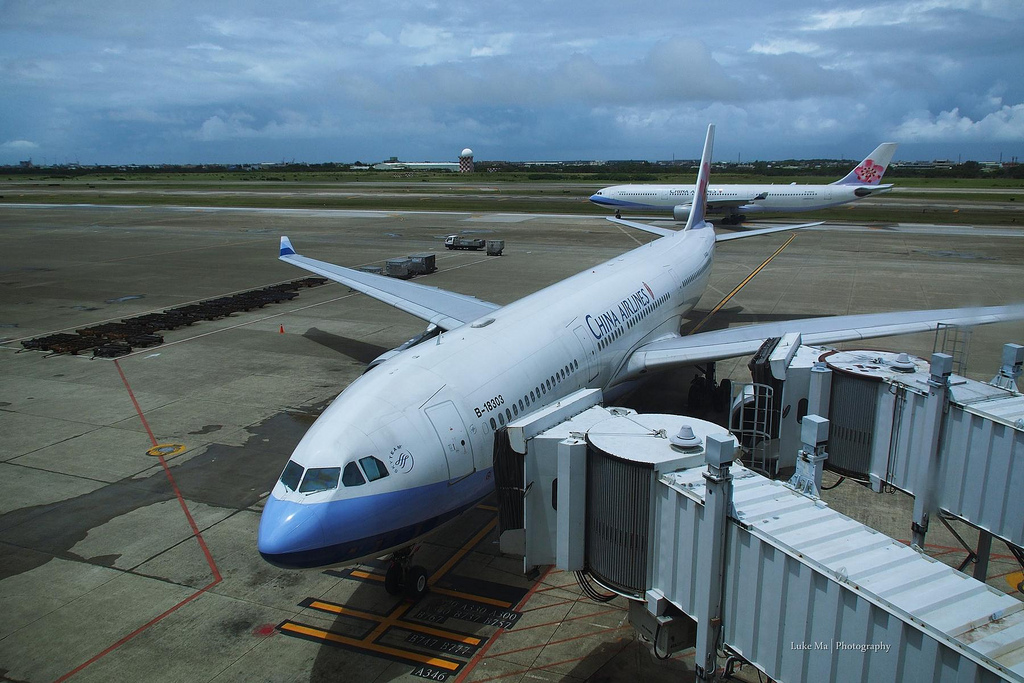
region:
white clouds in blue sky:
[40, 78, 107, 121]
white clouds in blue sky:
[292, 34, 359, 101]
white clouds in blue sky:
[122, 40, 186, 95]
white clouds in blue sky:
[245, 40, 323, 116]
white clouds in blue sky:
[672, 57, 800, 144]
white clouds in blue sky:
[599, 48, 666, 88]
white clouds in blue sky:
[418, 63, 496, 124]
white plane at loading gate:
[129, 153, 910, 628]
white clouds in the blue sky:
[59, 34, 151, 69]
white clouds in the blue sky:
[283, 43, 361, 86]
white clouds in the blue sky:
[256, 131, 339, 152]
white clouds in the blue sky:
[423, 17, 589, 122]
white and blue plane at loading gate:
[154, 124, 872, 586]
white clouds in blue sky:
[116, 28, 164, 66]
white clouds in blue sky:
[405, 78, 497, 113]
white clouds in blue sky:
[607, 48, 697, 105]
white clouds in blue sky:
[281, 28, 327, 71]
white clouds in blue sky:
[386, 53, 473, 117]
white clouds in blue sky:
[275, 72, 345, 127]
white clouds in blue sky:
[146, 40, 208, 105]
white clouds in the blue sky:
[286, 65, 367, 117]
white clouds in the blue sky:
[433, 30, 485, 78]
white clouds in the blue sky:
[596, 37, 648, 82]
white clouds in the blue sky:
[319, 42, 395, 99]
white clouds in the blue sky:
[231, 37, 296, 95]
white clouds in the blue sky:
[536, 8, 609, 72]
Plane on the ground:
[245, 115, 1018, 659]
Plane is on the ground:
[210, 105, 1021, 603]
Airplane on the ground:
[219, 117, 1019, 617]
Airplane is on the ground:
[236, 100, 1015, 600]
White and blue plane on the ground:
[222, 100, 1019, 606]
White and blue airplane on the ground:
[239, 99, 1015, 611]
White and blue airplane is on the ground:
[234, 98, 1019, 610]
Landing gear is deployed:
[359, 533, 446, 610]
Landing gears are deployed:
[375, 336, 745, 616]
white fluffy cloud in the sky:
[538, 95, 608, 203]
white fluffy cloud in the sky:
[681, 69, 748, 153]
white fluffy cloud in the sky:
[236, 48, 326, 153]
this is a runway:
[94, 23, 883, 498]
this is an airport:
[165, 80, 931, 634]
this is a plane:
[230, 184, 747, 578]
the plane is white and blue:
[195, 150, 750, 542]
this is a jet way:
[566, 396, 800, 631]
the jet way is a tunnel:
[546, 437, 927, 679]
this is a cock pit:
[252, 425, 459, 657]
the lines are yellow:
[297, 573, 453, 653]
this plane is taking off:
[511, 142, 983, 269]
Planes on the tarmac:
[196, 155, 959, 621]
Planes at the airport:
[275, 139, 917, 592]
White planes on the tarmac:
[230, 155, 948, 590]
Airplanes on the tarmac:
[223, 127, 983, 641]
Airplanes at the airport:
[214, 148, 917, 583]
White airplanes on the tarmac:
[228, 130, 928, 593]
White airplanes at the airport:
[218, 141, 908, 598]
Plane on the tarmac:
[231, 170, 854, 658]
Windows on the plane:
[268, 440, 412, 494]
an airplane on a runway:
[258, 121, 1018, 565]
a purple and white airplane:
[260, 143, 1011, 576]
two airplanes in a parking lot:
[249, 121, 989, 574]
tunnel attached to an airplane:
[249, 222, 1018, 679]